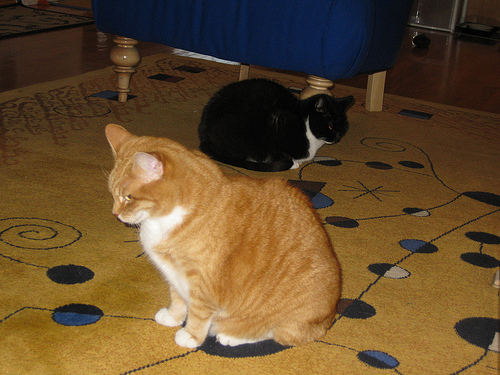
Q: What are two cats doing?
A: Sitting on a rug.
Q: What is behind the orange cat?
A: Black and white cat.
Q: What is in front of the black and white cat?
A: Orange cat.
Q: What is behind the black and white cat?
A: Table.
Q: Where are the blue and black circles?
A: On the rug.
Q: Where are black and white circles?
A: On the rug.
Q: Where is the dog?
A: There is no dog.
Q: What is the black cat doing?
A: Resting.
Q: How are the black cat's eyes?
A: Almost closed.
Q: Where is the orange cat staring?
A: The carpet.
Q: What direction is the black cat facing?
A: Right.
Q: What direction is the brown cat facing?
A: Left.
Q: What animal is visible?
A: Cats.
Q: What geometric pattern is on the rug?
A: Circle.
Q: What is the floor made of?
A: Wood.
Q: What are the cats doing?
A: Sitting down.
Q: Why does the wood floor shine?
A: Polished.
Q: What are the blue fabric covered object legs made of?
A: Wood.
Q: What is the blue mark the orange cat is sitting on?
A: Design in rug.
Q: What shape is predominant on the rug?
A: Circles.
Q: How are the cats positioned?
A: Sitting.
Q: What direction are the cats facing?
A: Left and right.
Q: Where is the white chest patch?
A: On both cats.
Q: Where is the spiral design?
A: On the rug.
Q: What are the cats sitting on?
A: An area rug.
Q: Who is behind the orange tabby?
A: A black and white cat.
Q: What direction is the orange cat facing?
A: Left.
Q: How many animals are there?
A: Two.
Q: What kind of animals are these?
A: Cats.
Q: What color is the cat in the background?
A: Black and white.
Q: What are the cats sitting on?
A: Rug.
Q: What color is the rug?
A: Tan, blue and black.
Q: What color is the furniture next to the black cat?
A: Blue.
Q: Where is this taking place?
A: On a rug.